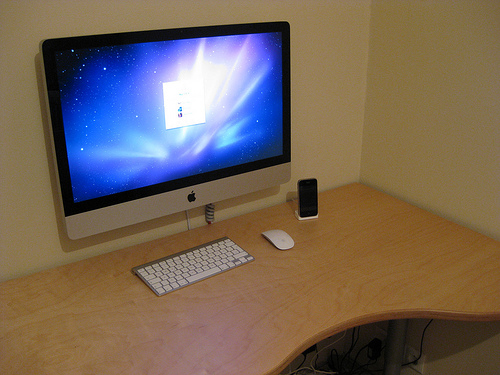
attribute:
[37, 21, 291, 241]
computer — apple brand, large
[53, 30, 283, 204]
screen — blue, large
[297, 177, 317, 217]
cellphone — black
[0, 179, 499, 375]
desk — brown, curved, wood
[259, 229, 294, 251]
mouse — white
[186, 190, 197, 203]
logo — black, apple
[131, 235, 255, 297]
keyboard — white, very small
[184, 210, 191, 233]
wire — gray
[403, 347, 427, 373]
outlet — beige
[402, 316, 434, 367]
cord — black